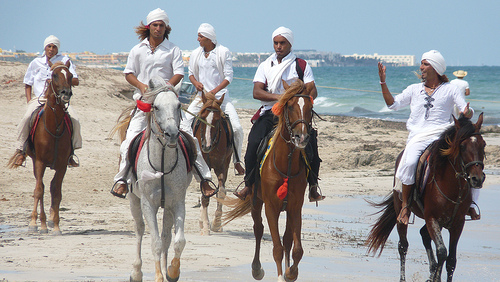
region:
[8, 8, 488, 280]
a group of men riding horses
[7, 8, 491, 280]
riding horses on the beach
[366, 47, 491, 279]
man riding horse on the beach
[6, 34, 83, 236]
man in all white riding horse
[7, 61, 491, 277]
sandy beach next to the water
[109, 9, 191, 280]
man in white riding a white horse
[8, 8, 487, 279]
men dressed in white riding horses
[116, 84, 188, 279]
white horse on beach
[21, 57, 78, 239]
brown horse on the beach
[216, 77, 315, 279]
brown horse with red bag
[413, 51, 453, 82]
head of a person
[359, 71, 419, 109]
arm of a person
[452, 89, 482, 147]
arm of a person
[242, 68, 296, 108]
arm of a person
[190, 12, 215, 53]
head of a person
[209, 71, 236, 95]
arm of a person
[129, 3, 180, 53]
head of a person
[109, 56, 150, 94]
arm of a person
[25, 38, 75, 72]
head of a person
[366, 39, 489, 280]
a person in white riding a horse.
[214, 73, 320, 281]
a brown horse on a beach.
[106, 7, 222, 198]
A man in white riding a white horse.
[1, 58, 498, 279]
A brown sandy beach.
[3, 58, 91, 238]
a large brown horse.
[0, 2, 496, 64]
a clear blue sky.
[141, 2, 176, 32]
A man riding a horse.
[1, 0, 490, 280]
A group of men on the beach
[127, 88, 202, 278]
The horse is the color white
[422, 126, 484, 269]
The horse is the color brown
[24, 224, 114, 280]
The sand on the beach is brown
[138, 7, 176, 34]
The man has on a hat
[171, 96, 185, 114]
The eye of the horse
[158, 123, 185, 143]
The nose of the horse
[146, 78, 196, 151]
The head of the horse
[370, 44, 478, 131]
The man is laughing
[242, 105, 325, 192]
The man has on black pants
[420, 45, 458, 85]
head of a person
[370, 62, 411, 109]
arm of a person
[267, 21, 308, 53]
head of a person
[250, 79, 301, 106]
arm of a person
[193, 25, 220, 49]
head of a person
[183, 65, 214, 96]
arm of a person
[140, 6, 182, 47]
head of a person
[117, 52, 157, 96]
arm of a person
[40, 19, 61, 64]
head of a person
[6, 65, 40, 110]
arm of a person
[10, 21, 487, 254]
several people on horses on the beach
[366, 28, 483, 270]
person in white on a horse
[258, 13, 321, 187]
person wearing a turban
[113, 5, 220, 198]
man is riding the horse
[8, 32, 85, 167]
man is riding the horse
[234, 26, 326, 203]
man is riding the horse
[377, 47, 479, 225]
lady is riding the horse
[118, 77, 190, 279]
horse is standing in the sand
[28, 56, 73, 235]
horse is standing in the sand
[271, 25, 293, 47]
scarf is on the guys head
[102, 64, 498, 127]
water is behind horse riders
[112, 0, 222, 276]
man riding on white horse